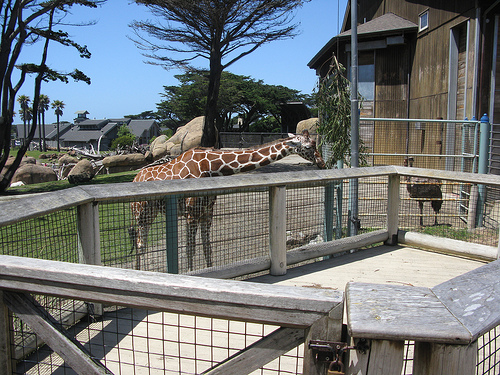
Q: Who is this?
A: No one.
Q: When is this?
A: Daytime.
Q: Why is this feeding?
A: Hungry.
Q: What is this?
A: Giraffe.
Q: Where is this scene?
A: In a zoo.